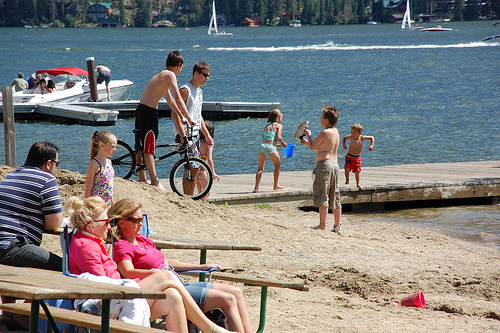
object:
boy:
[132, 47, 195, 188]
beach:
[0, 164, 497, 332]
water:
[370, 199, 499, 248]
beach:
[3, 23, 498, 183]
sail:
[205, 2, 230, 37]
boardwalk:
[158, 160, 500, 209]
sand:
[70, 178, 499, 331]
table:
[0, 264, 168, 333]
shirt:
[71, 233, 122, 280]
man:
[134, 51, 192, 188]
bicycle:
[96, 131, 214, 199]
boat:
[0, 75, 282, 127]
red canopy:
[35, 66, 92, 83]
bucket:
[284, 142, 296, 157]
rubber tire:
[171, 158, 214, 202]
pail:
[402, 291, 429, 309]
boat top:
[12, 66, 134, 105]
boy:
[298, 106, 341, 232]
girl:
[253, 109, 296, 193]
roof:
[86, 3, 115, 16]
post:
[0, 85, 18, 167]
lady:
[63, 193, 233, 333]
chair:
[58, 228, 91, 331]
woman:
[104, 195, 253, 332]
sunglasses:
[126, 215, 145, 223]